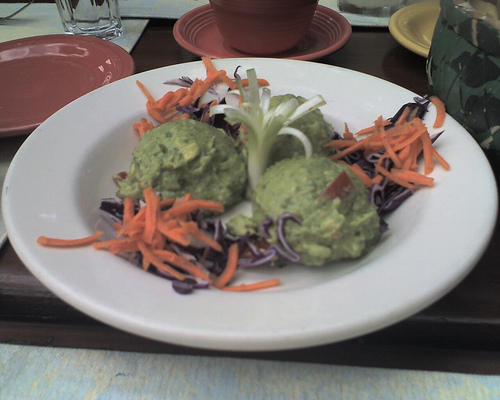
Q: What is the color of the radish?
A: Purple.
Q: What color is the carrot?
A: Orange.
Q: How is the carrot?
A: Shredded.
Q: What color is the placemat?
A: Brown.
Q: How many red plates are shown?
A: Two.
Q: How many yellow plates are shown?
A: One.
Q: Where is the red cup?
A: On the saucer.